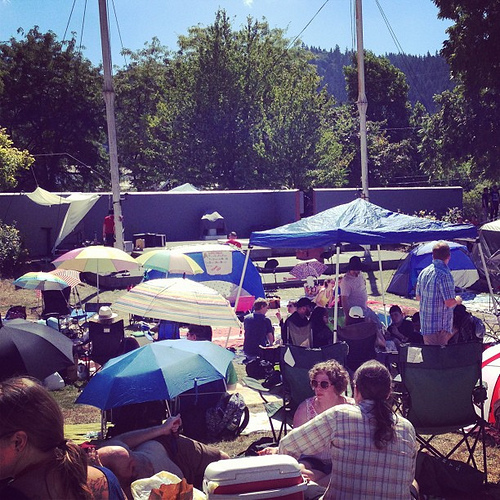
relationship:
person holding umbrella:
[92, 422, 231, 484] [73, 333, 241, 411]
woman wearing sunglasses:
[284, 358, 359, 422] [304, 371, 342, 392]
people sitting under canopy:
[234, 296, 500, 352] [241, 194, 484, 253]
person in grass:
[92, 422, 231, 484] [52, 384, 297, 467]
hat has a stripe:
[93, 304, 122, 326] [97, 310, 115, 322]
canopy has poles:
[241, 194, 484, 253] [239, 245, 499, 340]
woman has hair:
[284, 358, 359, 422] [301, 358, 353, 393]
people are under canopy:
[234, 296, 500, 352] [241, 194, 484, 253]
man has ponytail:
[283, 360, 421, 497] [367, 401, 401, 450]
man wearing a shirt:
[283, 360, 421, 497] [282, 401, 423, 499]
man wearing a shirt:
[417, 240, 462, 343] [406, 263, 464, 332]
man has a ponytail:
[283, 360, 421, 497] [367, 401, 401, 450]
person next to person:
[284, 297, 318, 357] [310, 305, 335, 349]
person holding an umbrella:
[92, 422, 231, 484] [73, 333, 241, 411]